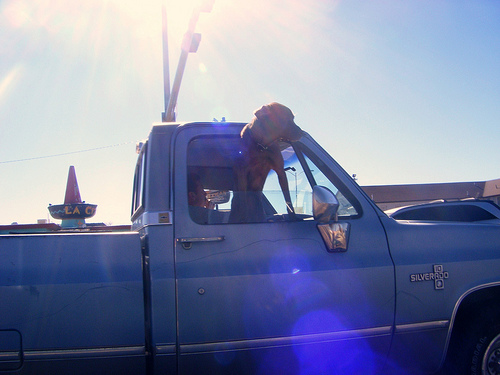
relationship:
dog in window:
[220, 90, 308, 223] [187, 118, 361, 227]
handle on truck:
[177, 229, 227, 244] [5, 112, 494, 362]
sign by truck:
[46, 162, 102, 234] [5, 112, 494, 362]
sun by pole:
[38, 0, 286, 141] [144, 1, 220, 125]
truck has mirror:
[5, 112, 494, 362] [308, 183, 349, 254]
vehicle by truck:
[395, 193, 500, 217] [5, 112, 494, 362]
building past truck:
[337, 170, 500, 211] [0, 112, 500, 375]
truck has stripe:
[5, 112, 494, 362] [3, 317, 450, 363]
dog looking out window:
[220, 90, 308, 223] [187, 118, 361, 227]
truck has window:
[5, 112, 494, 362] [187, 118, 361, 227]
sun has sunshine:
[38, 0, 286, 141] [1, 1, 500, 174]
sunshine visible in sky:
[1, 1, 500, 174] [3, 0, 496, 218]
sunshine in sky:
[1, 1, 500, 174] [3, 0, 496, 218]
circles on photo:
[256, 238, 398, 370] [8, 1, 500, 362]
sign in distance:
[46, 162, 102, 234] [6, 1, 499, 223]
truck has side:
[5, 112, 494, 362] [3, 116, 499, 368]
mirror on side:
[308, 183, 349, 254] [3, 116, 499, 368]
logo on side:
[412, 258, 450, 298] [3, 116, 499, 368]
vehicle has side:
[395, 193, 500, 217] [3, 116, 499, 368]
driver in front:
[190, 167, 238, 230] [189, 118, 367, 229]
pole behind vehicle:
[160, 1, 221, 116] [5, 112, 494, 362]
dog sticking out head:
[220, 90, 308, 223] [254, 98, 309, 146]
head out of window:
[254, 98, 309, 146] [187, 118, 361, 227]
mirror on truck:
[308, 183, 349, 254] [5, 112, 494, 362]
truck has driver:
[5, 112, 494, 362] [190, 167, 238, 230]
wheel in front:
[451, 316, 500, 368] [385, 209, 500, 365]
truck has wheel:
[5, 112, 494, 362] [451, 316, 500, 368]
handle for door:
[177, 229, 227, 244] [168, 118, 399, 369]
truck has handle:
[5, 112, 494, 362] [177, 229, 227, 244]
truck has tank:
[5, 112, 494, 362] [2, 323, 23, 371]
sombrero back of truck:
[47, 164, 99, 225] [5, 112, 494, 362]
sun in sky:
[38, 0, 286, 141] [3, 0, 496, 218]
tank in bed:
[2, 323, 23, 371] [1, 227, 146, 374]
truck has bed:
[5, 112, 494, 362] [1, 227, 146, 374]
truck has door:
[5, 112, 494, 362] [168, 118, 399, 369]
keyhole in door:
[196, 286, 206, 299] [168, 118, 399, 369]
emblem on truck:
[412, 258, 450, 298] [5, 112, 494, 362]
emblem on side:
[412, 258, 450, 298] [3, 116, 499, 368]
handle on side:
[177, 229, 227, 244] [3, 116, 499, 368]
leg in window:
[271, 151, 298, 217] [187, 118, 361, 227]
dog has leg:
[220, 90, 308, 223] [271, 151, 298, 217]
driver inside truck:
[190, 167, 238, 230] [5, 112, 494, 362]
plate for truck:
[408, 261, 451, 293] [5, 112, 494, 362]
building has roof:
[337, 170, 500, 211] [371, 174, 500, 199]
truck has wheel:
[5, 112, 494, 362] [451, 316, 500, 375]